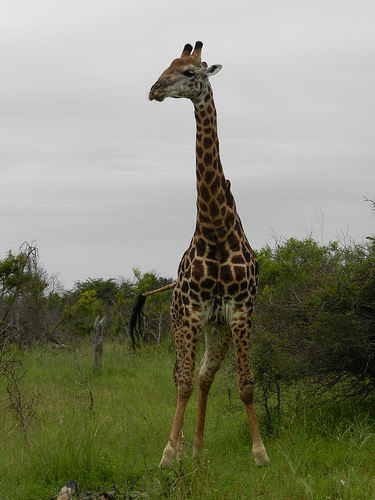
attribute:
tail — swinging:
[128, 280, 176, 352]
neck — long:
[190, 108, 224, 146]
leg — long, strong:
[233, 340, 261, 455]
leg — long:
[198, 346, 214, 456]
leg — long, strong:
[178, 349, 191, 464]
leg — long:
[172, 370, 177, 381]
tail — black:
[141, 288, 172, 300]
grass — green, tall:
[49, 441, 128, 462]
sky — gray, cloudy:
[243, 19, 366, 98]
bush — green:
[309, 318, 359, 379]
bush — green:
[76, 314, 93, 339]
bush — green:
[265, 260, 312, 284]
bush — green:
[75, 301, 99, 315]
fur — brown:
[236, 272, 242, 275]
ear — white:
[205, 62, 230, 79]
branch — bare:
[17, 395, 27, 403]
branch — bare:
[13, 378, 22, 382]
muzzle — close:
[154, 84, 169, 95]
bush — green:
[15, 281, 38, 308]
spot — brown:
[205, 138, 214, 148]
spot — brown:
[208, 110, 210, 113]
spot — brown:
[192, 107, 200, 110]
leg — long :
[158, 293, 218, 458]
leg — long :
[220, 254, 269, 464]